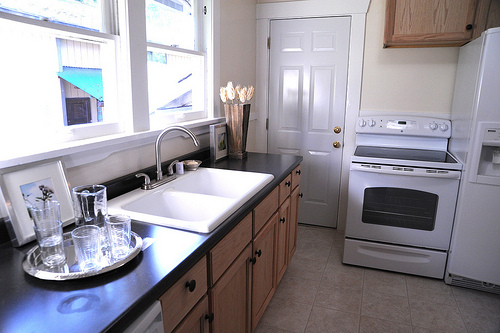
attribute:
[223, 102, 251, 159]
vase — full, brown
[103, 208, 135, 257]
glass — clear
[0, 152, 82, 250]
photot — silver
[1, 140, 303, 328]
counter — black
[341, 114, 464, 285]
oven — white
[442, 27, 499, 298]
fridge — new, white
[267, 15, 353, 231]
door — shiny, white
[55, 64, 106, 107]
awning — green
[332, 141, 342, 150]
knob — brass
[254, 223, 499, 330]
floor — tile, tiled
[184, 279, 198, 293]
pull — black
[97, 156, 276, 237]
sink — white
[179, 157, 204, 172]
soap dish — silver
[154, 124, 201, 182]
faucet — silver, curved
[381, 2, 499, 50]
cabinet — brown, wood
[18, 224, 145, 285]
tray — silver